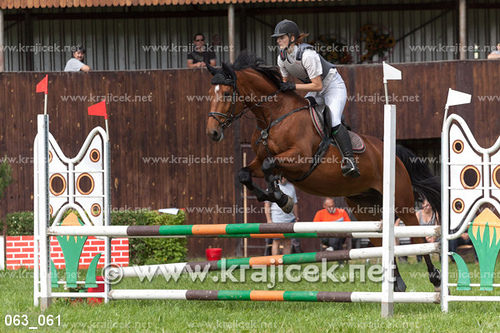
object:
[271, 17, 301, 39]
helmet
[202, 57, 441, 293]
horse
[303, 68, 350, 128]
pants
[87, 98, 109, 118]
flag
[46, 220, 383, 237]
stick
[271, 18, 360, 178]
woman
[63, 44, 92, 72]
people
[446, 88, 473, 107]
flag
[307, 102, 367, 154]
saddle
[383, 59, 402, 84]
flag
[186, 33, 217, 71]
man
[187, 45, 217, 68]
black shirt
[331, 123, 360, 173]
boot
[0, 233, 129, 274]
wall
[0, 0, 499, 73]
wall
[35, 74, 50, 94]
flag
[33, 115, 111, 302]
gate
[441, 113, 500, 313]
gate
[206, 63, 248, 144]
head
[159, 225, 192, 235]
green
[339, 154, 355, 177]
stirrup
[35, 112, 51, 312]
pole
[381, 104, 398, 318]
pole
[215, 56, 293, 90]
black mane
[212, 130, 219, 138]
nose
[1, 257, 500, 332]
grass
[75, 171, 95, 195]
circle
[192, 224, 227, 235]
orange